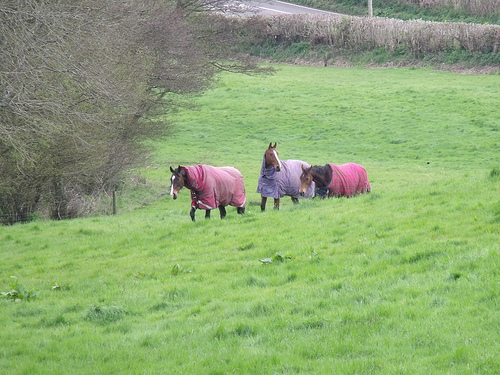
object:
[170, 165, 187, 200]
head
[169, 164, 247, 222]
horse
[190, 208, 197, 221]
leg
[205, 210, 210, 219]
leg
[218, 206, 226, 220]
leg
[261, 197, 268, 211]
leg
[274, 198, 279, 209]
leg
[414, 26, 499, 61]
bushes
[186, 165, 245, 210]
blanket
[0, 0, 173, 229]
tree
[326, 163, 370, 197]
cover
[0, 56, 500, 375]
field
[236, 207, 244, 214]
leg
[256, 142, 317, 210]
horse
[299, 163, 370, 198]
horse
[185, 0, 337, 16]
road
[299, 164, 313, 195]
head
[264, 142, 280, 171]
head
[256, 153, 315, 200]
covering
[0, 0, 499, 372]
outside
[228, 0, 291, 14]
line